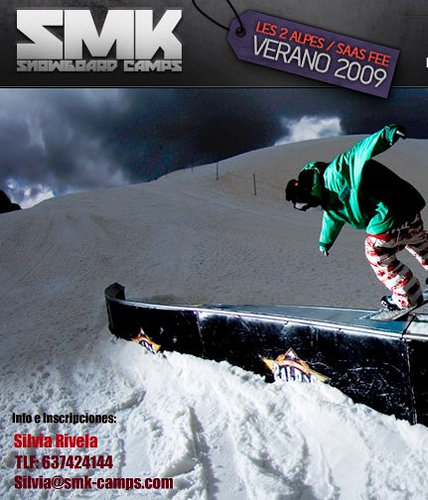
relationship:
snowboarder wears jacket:
[281, 121, 427, 319] [296, 125, 427, 258]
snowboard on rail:
[369, 283, 427, 322] [106, 280, 427, 365]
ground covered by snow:
[0, 132, 426, 498] [4, 135, 424, 497]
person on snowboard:
[286, 123, 427, 316] [357, 283, 427, 322]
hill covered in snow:
[0, 133, 426, 498] [4, 135, 424, 497]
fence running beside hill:
[152, 150, 323, 213] [0, 133, 426, 498]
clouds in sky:
[0, 86, 426, 209] [1, 88, 426, 210]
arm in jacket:
[352, 121, 405, 167] [296, 125, 427, 258]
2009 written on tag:
[333, 57, 388, 89] [236, 8, 424, 101]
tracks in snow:
[2, 183, 425, 498] [4, 135, 424, 497]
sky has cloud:
[1, 88, 426, 210] [272, 111, 342, 146]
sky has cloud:
[1, 88, 426, 210] [100, 91, 290, 184]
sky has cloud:
[1, 88, 426, 210] [0, 89, 133, 196]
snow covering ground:
[4, 135, 424, 497] [0, 132, 426, 498]